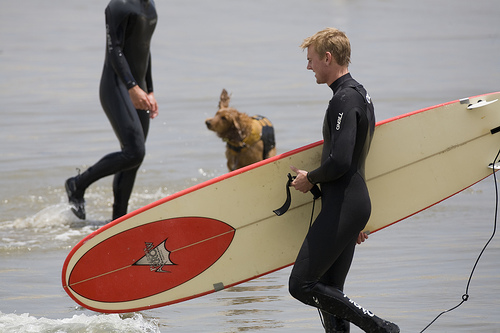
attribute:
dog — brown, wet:
[206, 88, 277, 172]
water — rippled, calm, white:
[0, 1, 498, 332]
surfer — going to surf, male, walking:
[289, 25, 401, 332]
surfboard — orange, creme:
[63, 91, 500, 313]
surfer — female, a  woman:
[64, 1, 158, 221]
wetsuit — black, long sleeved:
[288, 72, 400, 331]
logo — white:
[335, 110, 344, 130]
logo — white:
[105, 21, 114, 53]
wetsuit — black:
[74, 1, 158, 219]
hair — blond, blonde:
[300, 27, 353, 67]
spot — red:
[69, 216, 235, 303]